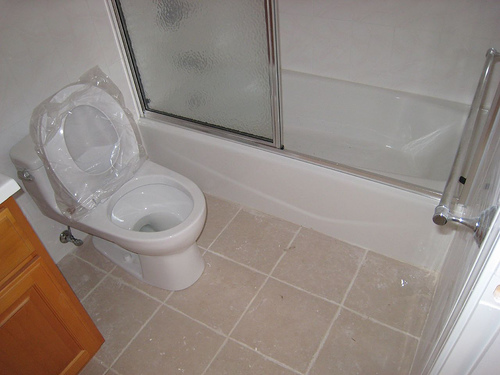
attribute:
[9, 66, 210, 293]
toilet — white, ceramic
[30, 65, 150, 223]
wrapping — plastic, clear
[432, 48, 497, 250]
bar — metal, silver, towel rack, empty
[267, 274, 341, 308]
groove — small, white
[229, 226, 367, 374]
tiles — beige, tan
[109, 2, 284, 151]
door — closed, glass, sliding, translucent, open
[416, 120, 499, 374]
wall — tiled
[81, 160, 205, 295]
bowl — white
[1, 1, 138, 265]
wall — white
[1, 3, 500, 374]
bathroom — clean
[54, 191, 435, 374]
floor — tile, tiled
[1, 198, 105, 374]
cabinet — oak, wood, light brown, wooden, vanity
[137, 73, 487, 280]
bathtub — white, empty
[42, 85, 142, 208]
lid — covered, up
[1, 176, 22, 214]
corner — sink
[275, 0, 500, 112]
tile — white